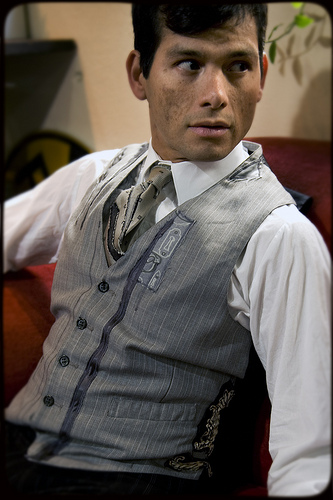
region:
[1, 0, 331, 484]
Man wearing a tan vest with buttons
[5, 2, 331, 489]
Man wearing long sleeve white t-shirt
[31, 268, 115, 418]
Four black buttons on vest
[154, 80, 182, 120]
Spot on face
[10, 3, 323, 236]
Man face to the right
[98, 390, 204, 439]
Pocket of vest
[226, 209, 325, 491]
White long sleeve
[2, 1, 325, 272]
Man facing to the right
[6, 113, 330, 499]
Man sits on a red couch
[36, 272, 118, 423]
Four grey buttons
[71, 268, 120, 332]
The top two buttons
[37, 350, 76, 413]
The bottom two buttons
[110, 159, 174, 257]
A mans tie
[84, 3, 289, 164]
The head of a man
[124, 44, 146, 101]
The ear of a man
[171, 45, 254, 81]
The eyes of a man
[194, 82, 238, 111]
The nose of a man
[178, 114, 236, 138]
The mouth of a man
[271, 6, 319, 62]
Green leaves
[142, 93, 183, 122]
There are dark spots on the man's face.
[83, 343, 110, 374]
There is a large blue line on the man's vest.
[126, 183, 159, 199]
The man is wearing a tie.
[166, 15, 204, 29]
The man has dark hair.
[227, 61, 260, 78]
The man had dark eyes.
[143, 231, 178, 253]
There is a patch on the vest.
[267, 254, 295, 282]
The under shirt is white.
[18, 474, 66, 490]
The pants are black.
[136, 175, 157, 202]
There are squares on the tie.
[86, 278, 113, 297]
The buttons are black.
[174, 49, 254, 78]
the mans eyes looking to the right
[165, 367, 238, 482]
gold stitching on the side of a vest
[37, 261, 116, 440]
four buttons on the front of a vest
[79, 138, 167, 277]
gold and gray tie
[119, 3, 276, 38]
black hair on the mans head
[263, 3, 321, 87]
branch with leaves in the background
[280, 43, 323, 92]
shadow on the wall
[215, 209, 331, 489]
sleeve of the mans white shirt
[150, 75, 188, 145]
blemish on the mans face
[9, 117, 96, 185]
round yellow and black object out of focus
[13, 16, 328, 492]
Interior shot, showing person on furniture.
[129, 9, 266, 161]
Male, Caucasian face, angled left.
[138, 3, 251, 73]
Black hair with sideburns, sweeping low on medium sized brow.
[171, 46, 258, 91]
Short brows with wary eyes, looking left.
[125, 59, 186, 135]
Large ear and damaged skin.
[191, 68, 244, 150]
An aquiline nose and wide lips.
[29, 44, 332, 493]
Male, wearing white, dress shirt, tie and blue vest with button-down front.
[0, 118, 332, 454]
Red furniture item, enveloping man.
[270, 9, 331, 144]
Pinkish wall with shadows and plant life.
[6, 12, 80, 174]
Additional furniture elements in corner of room.